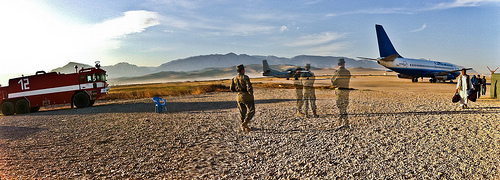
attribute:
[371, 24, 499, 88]
wing — large, blue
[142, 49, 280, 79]
mountain — distant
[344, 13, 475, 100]
airplane — parked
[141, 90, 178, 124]
chair — light blue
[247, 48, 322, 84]
airplane — taking off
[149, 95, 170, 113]
chair — small, blue, plastic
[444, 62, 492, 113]
people — disembarking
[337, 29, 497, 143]
plane — see through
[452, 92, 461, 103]
suitcase — black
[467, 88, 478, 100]
suitcase — black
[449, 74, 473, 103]
thawb — white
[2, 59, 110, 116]
firetruck — parked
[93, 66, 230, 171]
plains — dry, flat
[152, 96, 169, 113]
chair — blue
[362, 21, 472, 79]
jet — light colored, jet plane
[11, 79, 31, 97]
number — 12